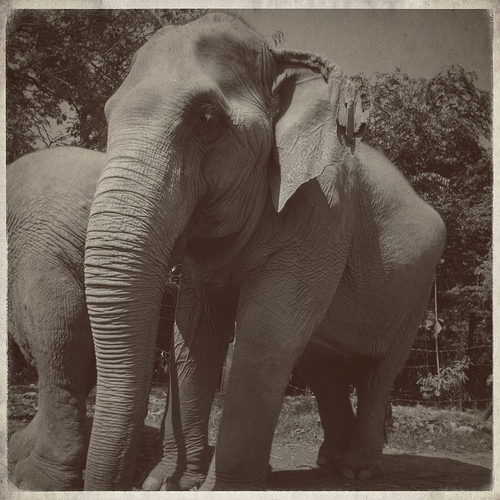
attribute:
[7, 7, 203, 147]
tree — tall, big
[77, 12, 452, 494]
elephant — posing, huge, standing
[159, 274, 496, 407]
fence — wire, metal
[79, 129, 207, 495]
trunk — long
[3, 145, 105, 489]
elephant — posing, huge, standing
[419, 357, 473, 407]
leaves — growing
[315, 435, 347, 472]
foot — rear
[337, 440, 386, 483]
foot — rear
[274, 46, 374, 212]
ear — large, flapping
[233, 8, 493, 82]
sky — above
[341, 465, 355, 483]
toe — large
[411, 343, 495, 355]
wire — barbed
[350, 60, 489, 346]
tree — tall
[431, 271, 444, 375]
pole — wooden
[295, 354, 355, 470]
leg — hind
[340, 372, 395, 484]
leg — hind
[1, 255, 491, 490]
park — wired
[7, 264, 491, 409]
area — bushy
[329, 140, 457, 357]
belly — big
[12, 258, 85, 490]
leg — back